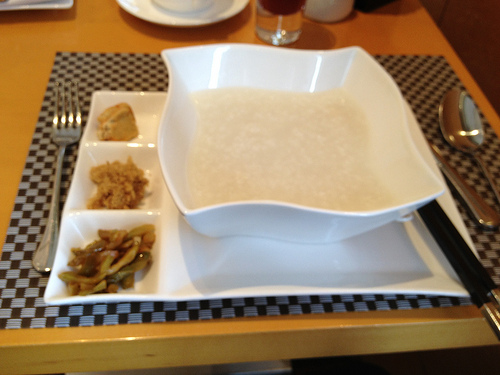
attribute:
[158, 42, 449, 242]
bowl — white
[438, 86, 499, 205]
spoon — silver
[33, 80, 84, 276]
fork — silver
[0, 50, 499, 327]
placemat — gray, checkered, black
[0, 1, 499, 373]
table — brown, wood, wooden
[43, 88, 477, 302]
plate — white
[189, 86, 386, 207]
soup — white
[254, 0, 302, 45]
glass — clear, small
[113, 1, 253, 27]
saucer — white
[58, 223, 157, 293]
beans — green, cooked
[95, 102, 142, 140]
paste — brown